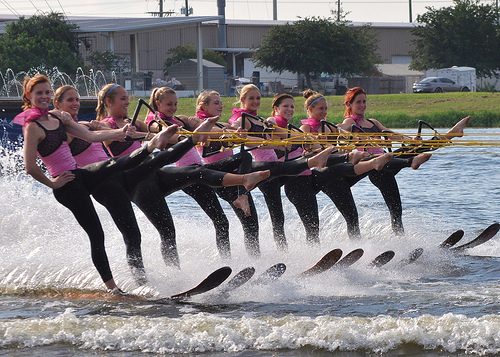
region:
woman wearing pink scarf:
[12, 75, 117, 282]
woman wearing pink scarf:
[54, 108, 173, 263]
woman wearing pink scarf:
[135, 84, 247, 262]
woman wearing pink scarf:
[331, 85, 425, 253]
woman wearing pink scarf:
[84, 97, 210, 230]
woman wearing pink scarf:
[18, 81, 232, 348]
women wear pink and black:
[16, 77, 477, 306]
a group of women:
[20, 62, 496, 302]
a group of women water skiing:
[19, 55, 473, 355]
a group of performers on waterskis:
[23, 56, 496, 323]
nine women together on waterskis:
[19, 43, 496, 270]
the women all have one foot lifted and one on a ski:
[17, 56, 498, 311]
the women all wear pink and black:
[11, 44, 453, 314]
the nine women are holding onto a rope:
[27, 46, 493, 310]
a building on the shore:
[29, 5, 484, 112]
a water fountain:
[7, 55, 147, 125]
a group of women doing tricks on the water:
[23, 54, 498, 349]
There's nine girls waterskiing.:
[13, 63, 498, 296]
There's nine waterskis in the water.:
[56, 216, 498, 293]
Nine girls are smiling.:
[18, 75, 380, 137]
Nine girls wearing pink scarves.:
[14, 104, 379, 139]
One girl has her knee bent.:
[211, 150, 267, 223]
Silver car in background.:
[411, 69, 470, 97]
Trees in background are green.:
[1, 2, 499, 86]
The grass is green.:
[122, 87, 499, 134]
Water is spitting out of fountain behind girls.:
[0, 67, 133, 107]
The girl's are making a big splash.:
[1, 143, 499, 293]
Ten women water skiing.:
[16, 54, 475, 311]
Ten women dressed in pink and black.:
[11, 65, 436, 252]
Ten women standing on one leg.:
[11, 70, 467, 300]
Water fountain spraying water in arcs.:
[0, 60, 150, 110]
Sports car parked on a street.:
[370, 65, 472, 106]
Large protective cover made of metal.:
[1, 10, 256, 85]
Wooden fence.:
[335, 65, 495, 90]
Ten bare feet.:
[125, 110, 480, 190]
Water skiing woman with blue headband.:
[295, 80, 340, 285]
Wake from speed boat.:
[2, 271, 497, 347]